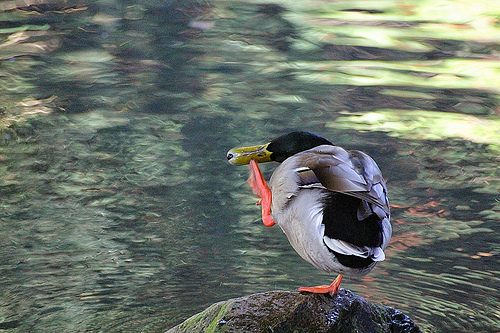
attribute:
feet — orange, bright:
[235, 164, 273, 221]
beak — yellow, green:
[228, 145, 278, 176]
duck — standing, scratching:
[253, 128, 423, 271]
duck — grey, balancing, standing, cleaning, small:
[211, 124, 487, 329]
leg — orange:
[303, 270, 357, 303]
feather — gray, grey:
[299, 165, 366, 196]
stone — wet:
[251, 288, 403, 332]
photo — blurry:
[30, 21, 465, 309]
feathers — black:
[327, 183, 395, 248]